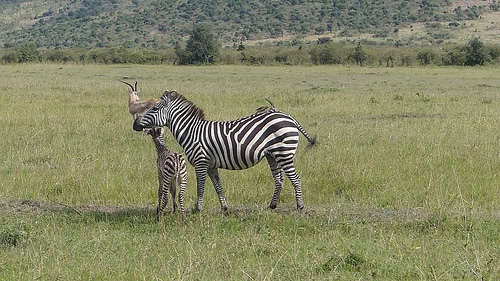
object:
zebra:
[131, 89, 320, 216]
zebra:
[142, 127, 191, 226]